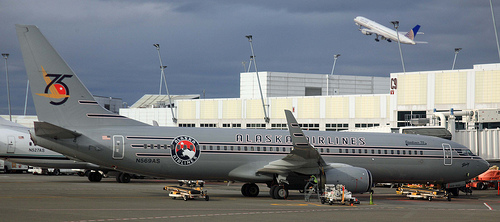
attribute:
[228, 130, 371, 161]
plane — Alaska Airlines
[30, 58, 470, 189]
gray plane — grey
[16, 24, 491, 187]
plane — grey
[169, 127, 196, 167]
symbol — Red and blue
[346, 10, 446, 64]
plane — white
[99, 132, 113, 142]
flag — US, printed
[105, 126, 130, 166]
door — closed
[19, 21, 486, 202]
jet — large, grey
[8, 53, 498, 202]
plane — grey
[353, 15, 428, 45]
plane — white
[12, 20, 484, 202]
plane — grey